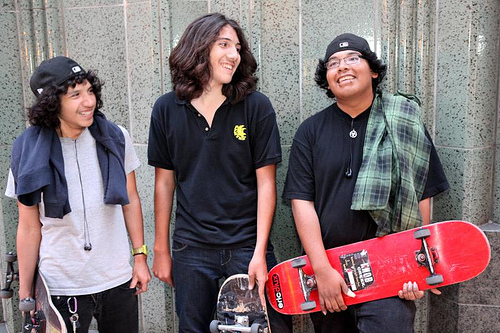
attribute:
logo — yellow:
[233, 122, 248, 142]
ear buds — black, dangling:
[73, 142, 94, 252]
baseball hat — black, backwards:
[30, 55, 87, 108]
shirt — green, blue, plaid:
[352, 90, 430, 235]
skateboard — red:
[267, 218, 491, 315]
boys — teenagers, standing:
[4, 14, 450, 331]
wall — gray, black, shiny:
[0, 0, 499, 331]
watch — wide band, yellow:
[134, 244, 148, 253]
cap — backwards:
[323, 34, 371, 59]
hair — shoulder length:
[169, 12, 258, 104]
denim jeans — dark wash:
[174, 238, 292, 331]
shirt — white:
[5, 125, 137, 295]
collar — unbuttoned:
[175, 90, 235, 138]